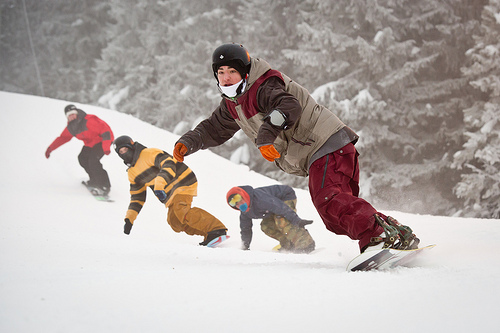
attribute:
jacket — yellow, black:
[120, 140, 197, 223]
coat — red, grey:
[180, 57, 359, 178]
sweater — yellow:
[124, 147, 199, 222]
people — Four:
[45, 40, 417, 271]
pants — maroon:
[313, 141, 401, 246]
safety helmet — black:
[206, 42, 250, 69]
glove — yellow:
[257, 142, 281, 164]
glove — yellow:
[173, 142, 188, 159]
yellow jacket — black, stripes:
[123, 146, 198, 235]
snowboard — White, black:
[345, 247, 440, 271]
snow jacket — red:
[40, 111, 117, 161]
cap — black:
[211, 43, 251, 96]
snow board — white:
[39, 182, 135, 291]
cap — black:
[109, 135, 135, 157]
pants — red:
[312, 134, 433, 236]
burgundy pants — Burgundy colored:
[303, 141, 398, 247]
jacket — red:
[46, 114, 116, 155]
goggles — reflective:
[227, 195, 243, 205]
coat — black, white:
[120, 144, 202, 229]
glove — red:
[45, 148, 48, 155]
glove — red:
[104, 149, 111, 154]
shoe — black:
[356, 220, 399, 255]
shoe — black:
[386, 216, 421, 245]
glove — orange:
[258, 132, 281, 160]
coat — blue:
[239, 183, 303, 223]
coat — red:
[47, 110, 114, 154]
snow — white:
[295, 11, 407, 109]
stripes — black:
[145, 153, 195, 199]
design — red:
[215, 236, 223, 246]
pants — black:
[67, 146, 109, 189]